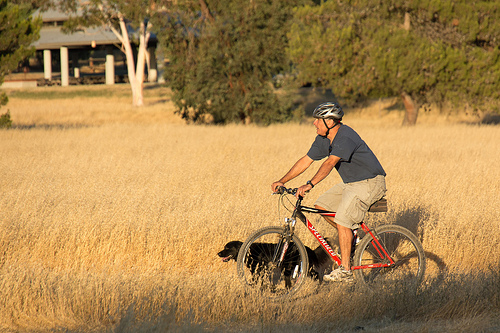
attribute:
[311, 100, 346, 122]
helmet — silver, gray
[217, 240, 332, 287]
dog — black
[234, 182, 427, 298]
bike — red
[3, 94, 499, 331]
grass — yellow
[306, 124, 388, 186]
shirt — blue, gray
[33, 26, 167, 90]
pavilion — medium sized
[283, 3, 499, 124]
tree — green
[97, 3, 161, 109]
trunk — white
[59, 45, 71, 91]
support — concrete, cement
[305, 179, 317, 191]
watch — black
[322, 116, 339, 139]
strap — black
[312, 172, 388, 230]
shorts — brown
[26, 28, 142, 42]
roof — gray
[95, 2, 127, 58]
branch — gray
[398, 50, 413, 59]
leaf — green